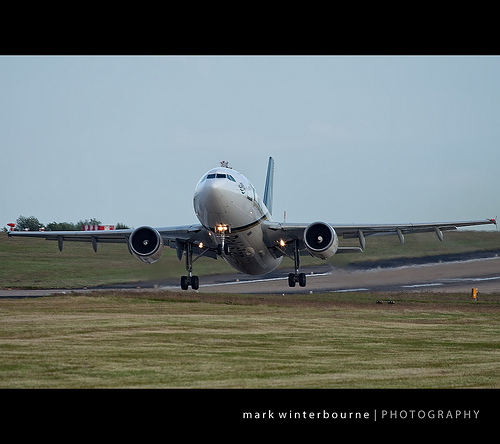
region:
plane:
[47, 150, 456, 288]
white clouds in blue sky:
[33, 102, 59, 132]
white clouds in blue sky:
[67, 115, 107, 153]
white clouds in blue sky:
[120, 60, 165, 98]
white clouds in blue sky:
[44, 101, 76, 137]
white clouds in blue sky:
[15, 129, 53, 188]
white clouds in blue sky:
[123, 141, 183, 218]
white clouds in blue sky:
[200, 73, 257, 128]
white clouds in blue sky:
[325, 79, 380, 129]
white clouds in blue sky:
[326, 133, 389, 188]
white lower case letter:
[238, 410, 254, 420]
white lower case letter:
[252, 409, 261, 419]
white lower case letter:
[261, 410, 266, 417]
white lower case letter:
[266, 407, 275, 419]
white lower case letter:
[276, 409, 287, 418]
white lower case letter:
[288, 409, 293, 419]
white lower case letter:
[293, 410, 301, 419]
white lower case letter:
[300, 408, 307, 420]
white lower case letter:
[305, 409, 315, 420]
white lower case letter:
[313, 410, 323, 420]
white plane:
[42, 156, 416, 303]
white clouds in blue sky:
[25, 90, 65, 130]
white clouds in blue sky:
[332, 101, 392, 167]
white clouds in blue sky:
[351, 176, 401, 237]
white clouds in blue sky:
[81, 99, 125, 157]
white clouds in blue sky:
[32, 133, 86, 171]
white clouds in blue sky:
[414, 113, 468, 164]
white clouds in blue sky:
[298, 119, 362, 163]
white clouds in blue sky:
[218, 62, 266, 109]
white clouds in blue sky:
[317, 59, 354, 104]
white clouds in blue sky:
[401, 121, 452, 172]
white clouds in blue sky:
[305, 131, 339, 176]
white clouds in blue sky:
[150, 92, 202, 144]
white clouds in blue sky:
[202, 75, 239, 105]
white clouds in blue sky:
[52, 101, 103, 145]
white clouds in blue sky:
[70, 133, 144, 200]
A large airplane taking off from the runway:
[0, 165, 499, 308]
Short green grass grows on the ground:
[84, 308, 390, 384]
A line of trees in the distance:
[10, 212, 150, 247]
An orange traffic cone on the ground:
[465, 285, 487, 300]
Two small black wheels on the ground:
[285, 267, 316, 293]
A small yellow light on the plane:
[211, 218, 236, 238]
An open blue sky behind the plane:
[327, 91, 461, 192]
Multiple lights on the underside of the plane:
[190, 214, 293, 256]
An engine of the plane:
[302, 213, 350, 263]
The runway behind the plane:
[315, 247, 490, 300]